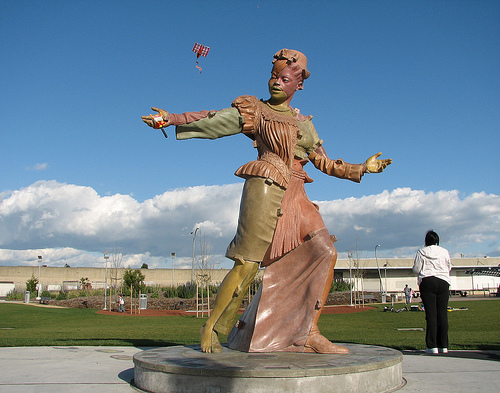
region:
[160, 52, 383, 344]
the statue is a woman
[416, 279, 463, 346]
the pants are black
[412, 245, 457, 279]
the shirt is white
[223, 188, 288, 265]
the dress is brown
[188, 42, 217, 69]
the kite is high up in the air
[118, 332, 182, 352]
shadow is on the ground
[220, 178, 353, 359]
the woman has two types of dress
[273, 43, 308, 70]
the hat is brown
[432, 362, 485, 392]
the floor is grey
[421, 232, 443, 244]
the hair is black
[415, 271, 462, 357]
woman's pants are black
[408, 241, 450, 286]
woman's shirt is white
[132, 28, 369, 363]
the statue is brown and green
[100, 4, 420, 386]
statue standing on concrete oval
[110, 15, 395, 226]
statue's arms are spread out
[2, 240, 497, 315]
building in the background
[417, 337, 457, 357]
woman's shoes are white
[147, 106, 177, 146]
red and white object in statue's hand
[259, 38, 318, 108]
statue is looking at right hand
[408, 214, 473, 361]
woman's back facing camera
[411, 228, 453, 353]
person standing on top of concrete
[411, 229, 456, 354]
person wearing a white hoodie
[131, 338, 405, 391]
round cement base under statue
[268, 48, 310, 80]
statue wearing a bonnet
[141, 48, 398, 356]
statue is green and pink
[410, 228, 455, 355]
person to the right of statue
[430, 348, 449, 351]
person wearing white shoes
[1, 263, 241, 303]
large low building behind statue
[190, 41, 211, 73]
kite is flying in the sky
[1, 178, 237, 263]
large white cloud beneath kite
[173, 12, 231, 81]
red kite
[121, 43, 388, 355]
statue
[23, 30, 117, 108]
white clouds in blue sky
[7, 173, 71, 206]
white clouds in blue sky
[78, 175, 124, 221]
white clouds in blue sky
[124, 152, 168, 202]
white clouds in blue sky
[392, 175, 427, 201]
white clouds in blue sky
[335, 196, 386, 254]
white clouds in blue sky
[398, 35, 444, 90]
white clouds in blue sky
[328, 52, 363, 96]
white clouds in blue sky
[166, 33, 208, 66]
kite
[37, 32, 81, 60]
white clouds in blue sky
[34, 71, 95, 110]
white clouds in blue sky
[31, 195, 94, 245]
white clouds in blue sky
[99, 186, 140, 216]
white clouds in blue sky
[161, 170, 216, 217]
white clouds in blue sky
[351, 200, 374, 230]
white clouds in blue sky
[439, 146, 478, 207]
white clouds in blue sky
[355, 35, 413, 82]
white clouds in blue sky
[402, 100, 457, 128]
white clouds in blue sky